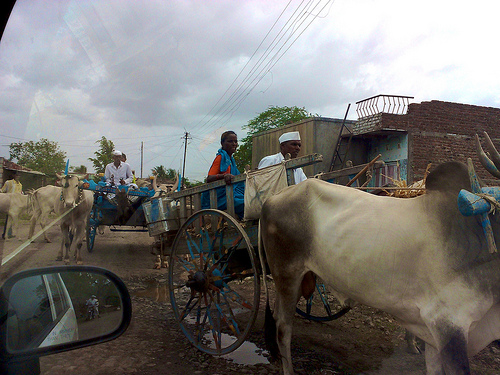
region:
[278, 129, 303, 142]
white hat on man's head.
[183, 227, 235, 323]
wheel on the cart.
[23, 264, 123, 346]
mirror on the vehicle.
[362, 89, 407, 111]
railing on the roof.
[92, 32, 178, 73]
clouds in the sky.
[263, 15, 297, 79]
wires in the air.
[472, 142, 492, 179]
antlers on the animal.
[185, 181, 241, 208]
wooden railing on cart.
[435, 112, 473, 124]
wall made of bricks.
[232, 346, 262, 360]
puddle on the ground.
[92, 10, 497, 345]
an animal pulling a buggy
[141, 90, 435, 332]
two people sitting on a buggy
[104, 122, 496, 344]
a buggy with two wheels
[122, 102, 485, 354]
a buggy being pulled by an animal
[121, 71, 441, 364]
a buggy going down the road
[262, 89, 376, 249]
a man wearing a white hat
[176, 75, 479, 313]
two people sitting in the buggy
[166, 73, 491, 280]
two people sitting on the buggy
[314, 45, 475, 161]
a balcony on top of a building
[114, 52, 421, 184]
power lines in the air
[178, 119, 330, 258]
A man and a woman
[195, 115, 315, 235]
Two people are on a wagon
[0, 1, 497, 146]
The sky is cloudy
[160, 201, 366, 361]
Wagon has two wheels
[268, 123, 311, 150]
Man is wearing a white hat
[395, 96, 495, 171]
A brick wall in the background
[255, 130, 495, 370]
An animal is in the foreground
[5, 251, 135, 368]
A car's rear view mirror in the foreground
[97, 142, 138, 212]
A man is in the background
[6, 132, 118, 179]
Tall trees are in the background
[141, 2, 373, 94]
Wires under a cloudy sky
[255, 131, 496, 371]
Body of a boney white ox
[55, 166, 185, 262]
Two white oxes pulling a wagon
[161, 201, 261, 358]
Large wheel with rusty blue spokes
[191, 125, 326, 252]
A man and a woman riding in a wagon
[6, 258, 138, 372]
Side view car mirror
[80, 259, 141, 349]
Person on a bike in a side mirror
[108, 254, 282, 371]
Puddles on a dirt street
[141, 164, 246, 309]
Metal pail attached to the side of a cart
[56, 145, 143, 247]
Man in white driving a blue wagon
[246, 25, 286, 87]
wires in the air.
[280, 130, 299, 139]
hat on man's head.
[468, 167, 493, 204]
antler of the animal.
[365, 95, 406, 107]
railing on the roof.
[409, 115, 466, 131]
wall made of brick.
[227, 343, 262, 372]
puddle on the ground.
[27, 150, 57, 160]
leaves on the tree.